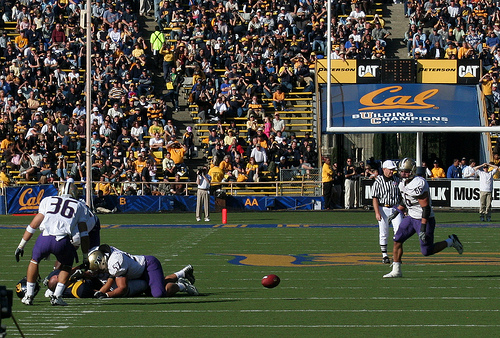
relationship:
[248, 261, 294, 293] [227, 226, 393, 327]
football on field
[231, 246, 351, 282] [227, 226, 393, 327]
logo on field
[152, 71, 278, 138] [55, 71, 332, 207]
fans in bleachers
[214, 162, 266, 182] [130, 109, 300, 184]
awning over coaches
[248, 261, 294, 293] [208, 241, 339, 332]
football on ground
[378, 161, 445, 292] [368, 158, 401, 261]
player and referee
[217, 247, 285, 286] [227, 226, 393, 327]
paint on field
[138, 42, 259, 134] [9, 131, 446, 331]
spectators watch game